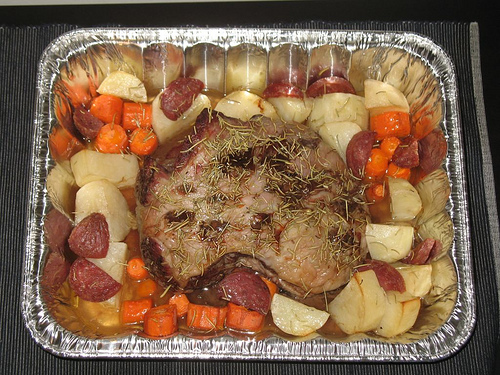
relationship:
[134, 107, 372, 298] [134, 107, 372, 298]
beef lining beef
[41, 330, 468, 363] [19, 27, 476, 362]
creases belonging to container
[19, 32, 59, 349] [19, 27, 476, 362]
creases belonging to container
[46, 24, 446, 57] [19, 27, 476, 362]
creases belonging to container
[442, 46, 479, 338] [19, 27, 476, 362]
creases belonging to container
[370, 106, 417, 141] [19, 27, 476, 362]
carrot in container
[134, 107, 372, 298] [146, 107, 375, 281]
beef in herbs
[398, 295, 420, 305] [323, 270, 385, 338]
edge of potato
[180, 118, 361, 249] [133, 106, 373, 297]
herbs on top of beef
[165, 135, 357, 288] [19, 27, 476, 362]
beef roasted in container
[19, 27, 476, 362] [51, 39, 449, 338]
container holding food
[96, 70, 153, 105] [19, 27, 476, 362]
veggies in container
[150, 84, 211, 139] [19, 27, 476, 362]
veggies in container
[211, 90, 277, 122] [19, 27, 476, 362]
veggies in container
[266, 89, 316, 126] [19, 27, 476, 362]
veggies in container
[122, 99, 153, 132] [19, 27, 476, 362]
veggies in container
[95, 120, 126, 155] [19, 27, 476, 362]
veggies in container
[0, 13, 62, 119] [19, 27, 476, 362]
mat under container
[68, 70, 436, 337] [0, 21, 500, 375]
food on mat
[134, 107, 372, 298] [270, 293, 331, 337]
beef by potato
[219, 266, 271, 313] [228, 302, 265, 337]
meat by vegetable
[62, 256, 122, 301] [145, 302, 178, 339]
meat by vegetable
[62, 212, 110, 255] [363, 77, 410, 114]
meat by vegetable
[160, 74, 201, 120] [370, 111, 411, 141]
meat by carrot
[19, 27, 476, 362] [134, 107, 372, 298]
container of beef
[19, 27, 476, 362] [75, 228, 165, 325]
container of vegetables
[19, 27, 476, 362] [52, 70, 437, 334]
container of food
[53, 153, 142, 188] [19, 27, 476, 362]
sliced potato in container